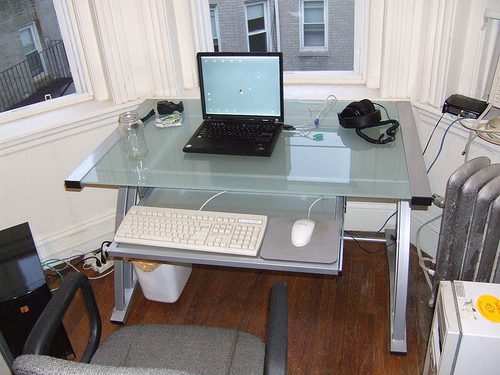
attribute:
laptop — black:
[181, 50, 285, 156]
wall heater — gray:
[425, 157, 497, 310]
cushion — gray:
[49, 311, 296, 373]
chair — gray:
[53, 279, 285, 371]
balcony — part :
[1, 37, 74, 112]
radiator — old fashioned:
[431, 159, 498, 294]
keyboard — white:
[112, 201, 274, 260]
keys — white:
[141, 215, 170, 237]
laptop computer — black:
[169, 45, 312, 152]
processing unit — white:
[421, 280, 498, 373]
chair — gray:
[11, 265, 296, 373]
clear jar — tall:
[95, 100, 208, 189]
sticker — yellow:
[476, 293, 496, 320]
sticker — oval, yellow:
[474, 292, 497, 324]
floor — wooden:
[2, 228, 444, 373]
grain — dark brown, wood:
[66, 231, 436, 372]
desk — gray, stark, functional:
[65, 96, 434, 356]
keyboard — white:
[114, 204, 267, 257]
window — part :
[211, 3, 361, 73]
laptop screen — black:
[185, 47, 305, 167]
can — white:
[131, 262, 192, 304]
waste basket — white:
[124, 256, 197, 306]